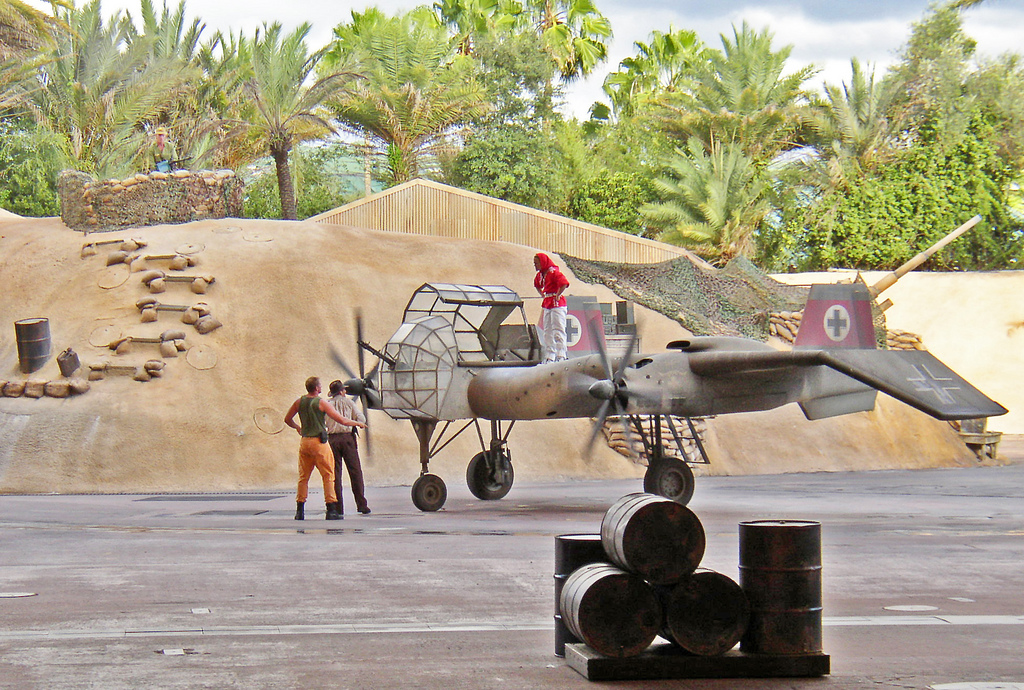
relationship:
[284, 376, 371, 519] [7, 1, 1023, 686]
man enjoying outdoors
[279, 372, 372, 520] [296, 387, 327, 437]
man wearing shirt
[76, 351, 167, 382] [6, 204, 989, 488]
step leading up hill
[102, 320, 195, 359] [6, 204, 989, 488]
step leading up hill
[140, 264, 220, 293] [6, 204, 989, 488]
step leading up hill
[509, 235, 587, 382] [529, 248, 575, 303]
man wears top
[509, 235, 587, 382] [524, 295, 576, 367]
man wears pants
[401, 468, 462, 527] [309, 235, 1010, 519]
wheel of plane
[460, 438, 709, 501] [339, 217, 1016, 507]
wheels of plane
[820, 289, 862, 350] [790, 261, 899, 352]
cross on stabilizer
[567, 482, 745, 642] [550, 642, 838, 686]
barrels on pallet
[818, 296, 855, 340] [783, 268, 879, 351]
decal on rudder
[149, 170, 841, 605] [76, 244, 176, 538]
people are enjoying outdoors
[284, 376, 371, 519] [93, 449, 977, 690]
man are enjoying outdoors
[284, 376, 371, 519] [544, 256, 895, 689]
man are enjoying outdoors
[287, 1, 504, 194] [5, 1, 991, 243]
tree in a city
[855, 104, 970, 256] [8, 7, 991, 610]
tree in a city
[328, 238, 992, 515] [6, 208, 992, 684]
airplane on airfield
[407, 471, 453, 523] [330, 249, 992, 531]
tire on plane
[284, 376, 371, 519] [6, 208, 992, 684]
man on airfield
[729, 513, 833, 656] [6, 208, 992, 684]
oil drum on airfield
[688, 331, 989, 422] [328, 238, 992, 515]
wing on airplane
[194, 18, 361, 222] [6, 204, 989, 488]
palm tree behind hill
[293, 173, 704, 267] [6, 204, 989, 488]
roof top behind hill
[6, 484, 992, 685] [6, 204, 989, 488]
airfield in front of hill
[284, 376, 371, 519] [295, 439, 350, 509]
man wearing pants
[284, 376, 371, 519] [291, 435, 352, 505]
man wearing pants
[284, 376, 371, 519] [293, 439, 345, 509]
man wearing pants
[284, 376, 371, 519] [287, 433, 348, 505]
man wearing pants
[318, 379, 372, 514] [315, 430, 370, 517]
man wearing pants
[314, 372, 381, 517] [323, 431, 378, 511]
man wearing pants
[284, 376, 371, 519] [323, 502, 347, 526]
man wearing shoe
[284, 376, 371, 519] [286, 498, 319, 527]
man wearing shoe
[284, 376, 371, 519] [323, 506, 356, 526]
man wearing shoe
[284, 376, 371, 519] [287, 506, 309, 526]
man wearing shoe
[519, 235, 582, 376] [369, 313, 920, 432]
woman standing on top of plane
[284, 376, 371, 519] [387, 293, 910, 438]
man men standing near propeller of plane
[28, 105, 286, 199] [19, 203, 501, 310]
person standing within enclosed area on top of hill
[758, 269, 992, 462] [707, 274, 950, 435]
large light brown gun barrel